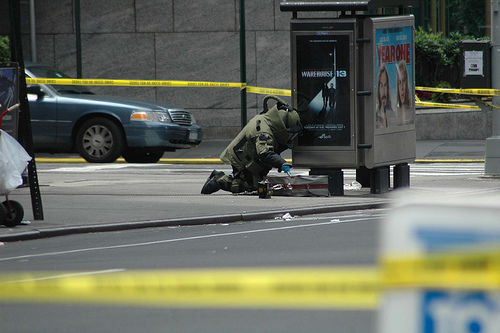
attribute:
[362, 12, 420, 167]
board —  with advertisment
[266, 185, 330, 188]
red line —  red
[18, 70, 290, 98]
ribbon —  yellow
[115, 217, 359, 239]
line — white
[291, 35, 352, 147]
poster ad —  poster's,  for Warehouse 13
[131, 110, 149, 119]
light —  orange,  signaling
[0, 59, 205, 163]
car —  blue green, blue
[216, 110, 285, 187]
suit —  for  bomb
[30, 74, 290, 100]
yellow ribbon —  yellow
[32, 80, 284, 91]
black letters —  black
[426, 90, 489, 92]
black letters —  black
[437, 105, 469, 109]
black letters —  black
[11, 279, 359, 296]
black letters —  black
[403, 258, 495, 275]
black letters —  black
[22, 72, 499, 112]
ribbon — yellow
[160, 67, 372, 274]
man —  in all green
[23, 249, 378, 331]
police tape —  yellow,  police's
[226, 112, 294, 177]
clothes —  green,  man's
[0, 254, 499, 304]
caution tape — for caution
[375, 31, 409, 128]
sign —  board's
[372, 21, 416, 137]
poster ad —  for Year One,  poster's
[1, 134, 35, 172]
garbage bag — white, hanging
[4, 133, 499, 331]
street — concrete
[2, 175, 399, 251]
curb — concrete